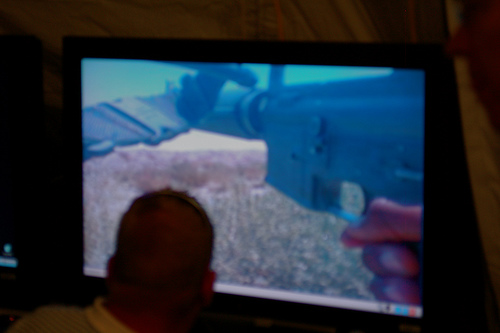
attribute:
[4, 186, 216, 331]
man — inside, standing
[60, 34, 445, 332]
tv — large, inside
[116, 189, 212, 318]
hair — dark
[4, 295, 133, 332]
shirt — orange, yellow, striped, polo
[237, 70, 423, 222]
gun — silver/blue, black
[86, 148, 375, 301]
ground — below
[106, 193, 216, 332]
head — big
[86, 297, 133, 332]
collar — yellow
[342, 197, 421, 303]
hand — balled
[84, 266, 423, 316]
bar — grey